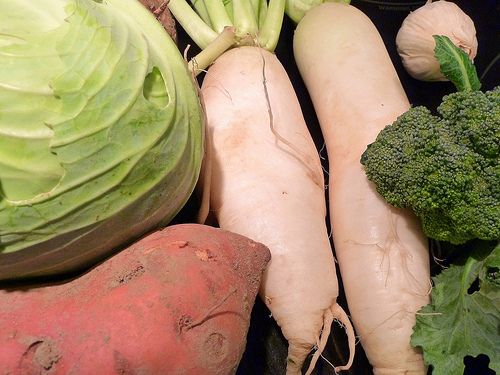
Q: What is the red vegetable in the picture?
A: Sweet potato.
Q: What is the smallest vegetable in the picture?
A: Garlic.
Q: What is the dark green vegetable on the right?
A: Broccoli.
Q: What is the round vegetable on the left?
A: A cabbage.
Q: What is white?
A: Turnip.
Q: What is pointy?
A: Veggie.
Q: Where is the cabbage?
A: With other veggies.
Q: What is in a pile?
A: Veggies.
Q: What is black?
A: Table.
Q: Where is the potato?
A: In the pile.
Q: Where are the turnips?
A: In the pile.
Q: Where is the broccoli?
A: In the pile.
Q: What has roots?
A: Sweet potato.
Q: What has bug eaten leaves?
A: Cabbage.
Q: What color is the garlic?
A: White.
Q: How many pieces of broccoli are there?
A: One.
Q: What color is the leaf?
A: Green.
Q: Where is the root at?
A: On the top of the parsnip.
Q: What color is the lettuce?
A: Green.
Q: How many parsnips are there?
A: Two.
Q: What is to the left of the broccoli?
A: Parsnip.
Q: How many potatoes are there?
A: One.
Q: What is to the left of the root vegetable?
A: Lettuce.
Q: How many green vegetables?
A: 3.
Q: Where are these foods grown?
A: Farm.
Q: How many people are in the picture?
A: 0.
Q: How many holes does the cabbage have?
A: 1.